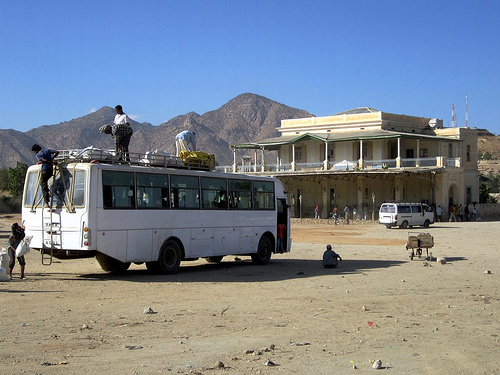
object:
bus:
[20, 146, 292, 275]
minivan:
[379, 202, 435, 229]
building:
[216, 106, 480, 221]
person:
[322, 244, 342, 269]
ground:
[0, 215, 498, 374]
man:
[31, 144, 60, 209]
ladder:
[41, 160, 62, 266]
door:
[276, 197, 287, 253]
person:
[315, 204, 321, 220]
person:
[332, 212, 338, 225]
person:
[343, 204, 350, 225]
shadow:
[75, 258, 408, 282]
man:
[113, 104, 130, 164]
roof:
[26, 160, 280, 182]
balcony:
[212, 157, 463, 176]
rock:
[484, 269, 492, 274]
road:
[2, 220, 498, 373]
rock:
[372, 359, 382, 369]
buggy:
[405, 232, 434, 261]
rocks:
[256, 349, 263, 355]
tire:
[159, 239, 182, 272]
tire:
[251, 235, 272, 266]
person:
[7, 222, 26, 281]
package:
[15, 235, 34, 258]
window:
[102, 170, 136, 211]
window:
[170, 187, 201, 210]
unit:
[190, 229, 216, 258]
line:
[0, 92, 314, 170]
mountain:
[194, 92, 318, 164]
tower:
[451, 103, 455, 126]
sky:
[1, 1, 499, 135]